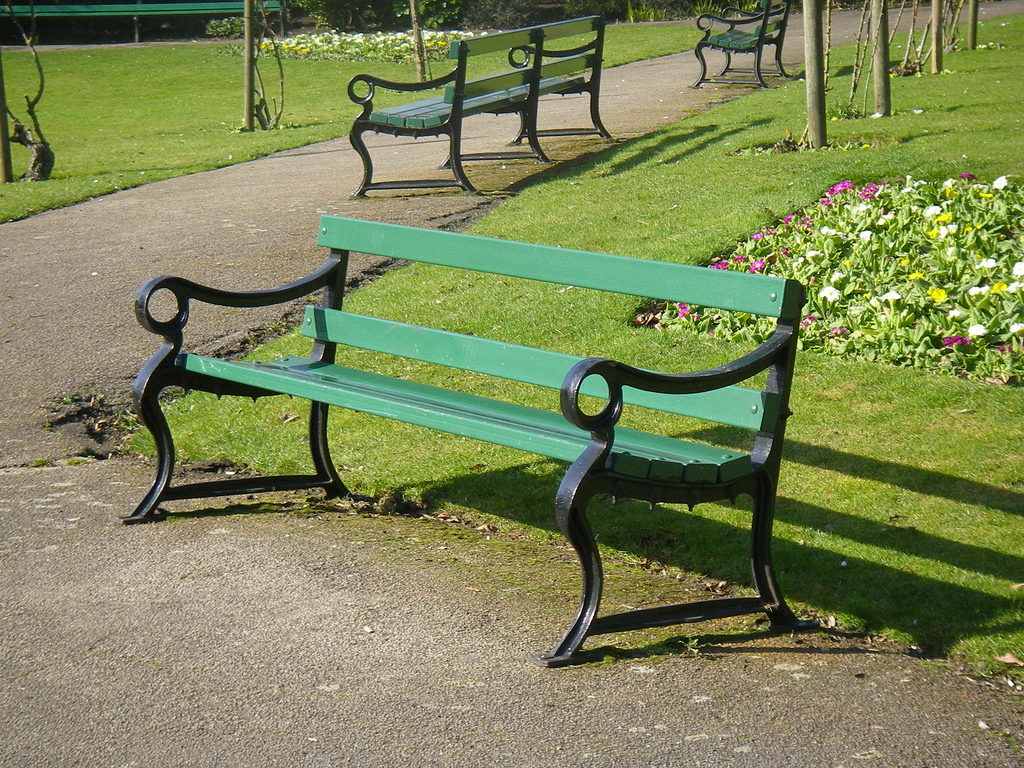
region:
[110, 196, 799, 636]
a green and black bench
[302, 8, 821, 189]
benches on a path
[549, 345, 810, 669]
black iron on the bench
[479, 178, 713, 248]
green grass near a path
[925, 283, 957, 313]
a yellow flower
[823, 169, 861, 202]
a pink flower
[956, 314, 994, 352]
a white flower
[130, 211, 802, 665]
a green and black park bench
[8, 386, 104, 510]
cracks in the pavement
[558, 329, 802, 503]
a black metal armrest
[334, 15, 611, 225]
a park bench on the sidewalk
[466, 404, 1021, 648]
a shadow cast onto the ground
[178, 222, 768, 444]
the green seat of a park bench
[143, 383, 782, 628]
grass beside a park bench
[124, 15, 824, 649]
three park benches on a sidewalk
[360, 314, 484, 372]
the board on the bench is green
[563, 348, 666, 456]
the fram of the bench is black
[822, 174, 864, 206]
the flower is purple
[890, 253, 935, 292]
the flower is yellow in color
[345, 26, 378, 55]
the flowers are white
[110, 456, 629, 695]
the bench is sitting on the sidewalk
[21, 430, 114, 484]
the sidewalk has a crack in it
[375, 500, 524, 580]
the grass cuttings are on the sidewalk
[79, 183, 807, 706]
green and black bench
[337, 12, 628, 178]
green and black bench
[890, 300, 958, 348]
colorful flowers with green leaves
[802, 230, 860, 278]
colorful flowers with green leaves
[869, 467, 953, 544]
short green and yellow grass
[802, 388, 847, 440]
short green and yellow grass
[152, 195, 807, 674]
green and black bench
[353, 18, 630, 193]
green and black bench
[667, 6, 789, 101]
green and black bench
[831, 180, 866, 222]
colorful flowers with green leaves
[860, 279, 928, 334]
colorful flowers with green leaves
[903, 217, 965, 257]
colorful flowers with green leaves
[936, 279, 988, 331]
colorful flowers with green leaves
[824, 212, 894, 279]
colorful flowers with green leaves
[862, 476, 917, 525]
short green and yellow grass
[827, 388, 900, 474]
short green and yellow grass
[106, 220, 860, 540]
a green bench in the park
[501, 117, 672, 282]
Fresh cut grass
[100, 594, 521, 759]
Concrete sidewalk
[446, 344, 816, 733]
Black metal armrests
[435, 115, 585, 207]
Grass under the bench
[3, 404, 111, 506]
A crack in the sidewalk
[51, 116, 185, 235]
Shadow from the tree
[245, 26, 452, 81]
White and yellow flowers growing in the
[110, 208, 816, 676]
Green empty bench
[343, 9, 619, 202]
Green empty bench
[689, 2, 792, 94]
Green empty bench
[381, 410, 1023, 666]
Shadow of the bench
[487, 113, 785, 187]
Shadow of the bench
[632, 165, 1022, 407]
Pink, yellow and white flower bed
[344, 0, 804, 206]
Two empty benches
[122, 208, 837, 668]
One empty bench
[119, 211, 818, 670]
the park bench is green and black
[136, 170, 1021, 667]
the flowers behind the park bench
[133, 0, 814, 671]
the park benches are green and black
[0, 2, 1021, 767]
the green grass near the park benches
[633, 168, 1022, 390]
the flowers are purple, white and yellow